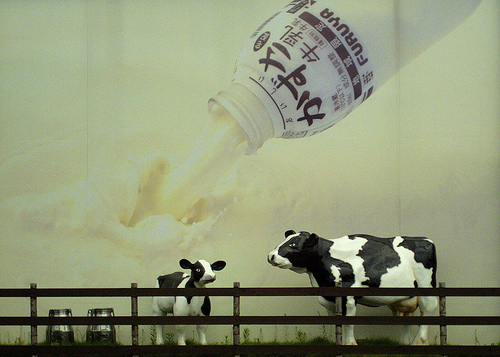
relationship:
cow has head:
[265, 225, 443, 350] [265, 227, 326, 275]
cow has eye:
[265, 225, 443, 350] [289, 240, 300, 251]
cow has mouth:
[265, 225, 443, 350] [271, 263, 291, 271]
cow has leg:
[265, 225, 443, 350] [341, 295, 359, 348]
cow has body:
[265, 225, 443, 350] [323, 232, 437, 308]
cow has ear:
[265, 225, 443, 350] [303, 231, 322, 253]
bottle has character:
[205, 1, 497, 156] [255, 40, 292, 78]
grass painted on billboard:
[0, 310, 483, 347] [1, 2, 497, 357]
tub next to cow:
[82, 305, 119, 349] [150, 259, 228, 346]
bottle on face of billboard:
[205, 1, 497, 156] [1, 2, 497, 357]